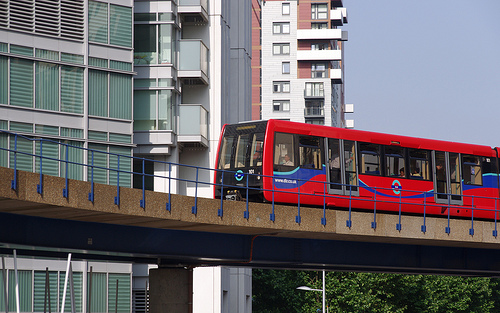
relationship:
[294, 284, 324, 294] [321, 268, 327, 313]
light on pole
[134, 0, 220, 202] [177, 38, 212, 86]
apartments have balconies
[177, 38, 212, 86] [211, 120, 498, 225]
balconies near train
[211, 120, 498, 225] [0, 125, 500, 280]
train on bridge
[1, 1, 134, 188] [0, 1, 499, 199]
building in background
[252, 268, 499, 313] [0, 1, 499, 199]
trees in background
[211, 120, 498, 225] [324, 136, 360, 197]
train has doors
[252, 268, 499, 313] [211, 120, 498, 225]
trees below train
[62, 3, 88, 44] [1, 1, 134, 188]
blinds in building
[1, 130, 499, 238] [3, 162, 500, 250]
railing along track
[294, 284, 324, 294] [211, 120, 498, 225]
light below train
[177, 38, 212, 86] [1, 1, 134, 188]
balconies on building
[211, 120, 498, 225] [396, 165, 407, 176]
train has passenger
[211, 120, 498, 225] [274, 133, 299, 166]
train has windows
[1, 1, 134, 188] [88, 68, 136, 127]
building has windows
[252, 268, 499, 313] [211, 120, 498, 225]
trees under train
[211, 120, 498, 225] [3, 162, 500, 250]
train on track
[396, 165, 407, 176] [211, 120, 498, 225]
passenger in train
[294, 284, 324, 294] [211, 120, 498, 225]
light under train